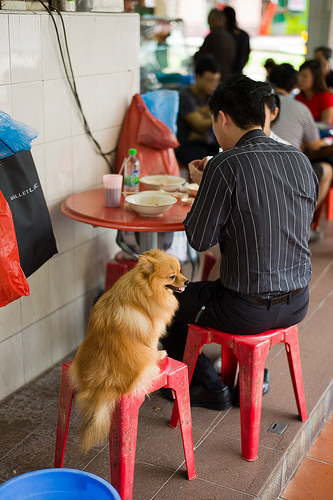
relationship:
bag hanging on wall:
[0, 137, 59, 279] [8, 62, 75, 148]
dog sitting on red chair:
[65, 248, 190, 457] [76, 329, 193, 471]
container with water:
[2, 467, 119, 499] [6, 487, 112, 498]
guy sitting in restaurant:
[159, 74, 320, 411] [0, 3, 321, 498]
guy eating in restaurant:
[159, 74, 320, 411] [0, 3, 321, 498]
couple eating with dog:
[166, 79, 318, 381] [64, 245, 191, 458]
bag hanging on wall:
[0, 188, 30, 307] [1, 9, 134, 401]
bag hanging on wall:
[0, 110, 59, 280] [1, 9, 134, 401]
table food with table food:
[60, 170, 183, 231] [102, 148, 199, 217]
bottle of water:
[120, 147, 136, 199] [123, 176, 138, 197]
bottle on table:
[120, 147, 136, 199] [61, 181, 199, 230]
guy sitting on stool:
[159, 74, 320, 411] [221, 330, 275, 385]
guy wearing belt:
[159, 74, 320, 411] [220, 280, 310, 304]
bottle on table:
[123, 148, 140, 198] [82, 198, 147, 230]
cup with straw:
[102, 174, 123, 210] [117, 154, 128, 172]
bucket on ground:
[0, 466, 124, 498] [2, 288, 322, 489]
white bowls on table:
[114, 186, 178, 213] [58, 186, 210, 251]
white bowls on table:
[139, 161, 184, 193] [58, 186, 210, 251]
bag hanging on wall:
[0, 137, 59, 279] [3, 4, 144, 419]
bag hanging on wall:
[0, 192, 30, 308] [3, 4, 144, 419]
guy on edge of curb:
[159, 74, 320, 411] [246, 416, 288, 490]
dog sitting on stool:
[64, 245, 191, 458] [48, 343, 201, 499]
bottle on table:
[123, 148, 140, 198] [70, 191, 112, 229]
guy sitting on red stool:
[159, 74, 320, 411] [179, 321, 316, 460]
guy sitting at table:
[159, 74, 320, 411] [60, 171, 213, 378]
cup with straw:
[103, 174, 124, 208] [117, 153, 125, 175]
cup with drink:
[103, 174, 124, 208] [104, 182, 121, 205]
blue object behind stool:
[1, 463, 121, 499] [52, 352, 204, 498]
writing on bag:
[7, 178, 42, 204] [1, 130, 59, 311]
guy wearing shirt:
[162, 72, 318, 410] [182, 129, 319, 294]